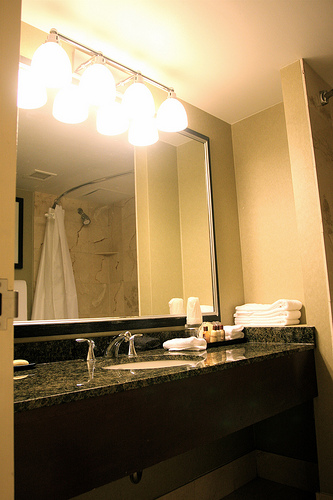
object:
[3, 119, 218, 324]
in mirror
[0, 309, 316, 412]
counter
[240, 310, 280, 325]
white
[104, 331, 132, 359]
faucets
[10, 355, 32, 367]
soap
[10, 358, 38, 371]
soap dish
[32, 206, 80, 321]
curtain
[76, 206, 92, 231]
shower head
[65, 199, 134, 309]
marbel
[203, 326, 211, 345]
bottles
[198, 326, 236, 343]
toiletries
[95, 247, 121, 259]
shelve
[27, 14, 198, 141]
row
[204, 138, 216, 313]
silver edge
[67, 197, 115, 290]
shower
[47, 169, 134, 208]
rod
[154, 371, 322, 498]
dark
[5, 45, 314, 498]
room's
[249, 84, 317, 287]
wall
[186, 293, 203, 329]
air freshener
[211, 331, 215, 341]
shampoo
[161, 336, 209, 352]
towel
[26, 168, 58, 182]
vent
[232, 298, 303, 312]
towel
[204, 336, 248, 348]
tray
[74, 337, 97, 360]
fixtures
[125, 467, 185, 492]
pipe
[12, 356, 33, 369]
bar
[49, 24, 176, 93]
bar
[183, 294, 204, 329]
stack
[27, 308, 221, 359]
counter top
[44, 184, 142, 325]
walls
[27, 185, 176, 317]
shower stall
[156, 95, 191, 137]
lights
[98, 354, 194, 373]
sink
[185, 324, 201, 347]
cups